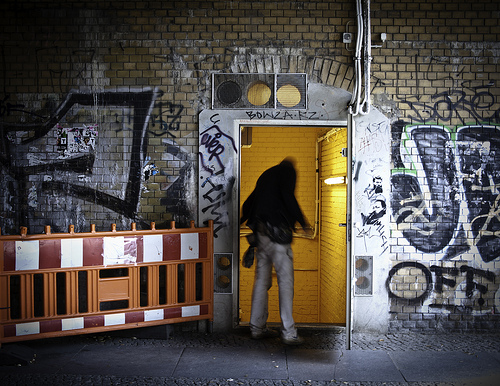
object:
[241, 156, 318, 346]
person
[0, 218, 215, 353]
gate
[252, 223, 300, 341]
pants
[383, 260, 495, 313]
graffiti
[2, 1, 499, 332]
wall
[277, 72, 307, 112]
vent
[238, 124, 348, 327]
door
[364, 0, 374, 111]
pipe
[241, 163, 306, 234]
jacket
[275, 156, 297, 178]
head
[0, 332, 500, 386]
sidewalk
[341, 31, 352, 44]
light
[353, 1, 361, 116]
wire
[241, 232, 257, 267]
bag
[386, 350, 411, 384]
line